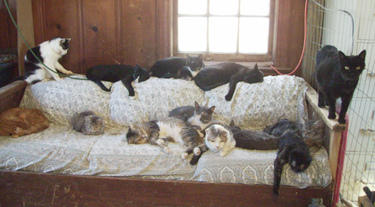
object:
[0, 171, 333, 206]
panel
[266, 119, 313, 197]
cat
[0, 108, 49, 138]
brown cat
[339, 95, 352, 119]
arm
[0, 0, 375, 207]
wall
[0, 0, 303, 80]
wood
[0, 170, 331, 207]
wood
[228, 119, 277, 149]
cat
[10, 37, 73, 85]
cat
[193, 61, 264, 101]
cat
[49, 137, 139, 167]
material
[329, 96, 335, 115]
arm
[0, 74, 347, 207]
couch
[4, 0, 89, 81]
cord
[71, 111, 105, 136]
cat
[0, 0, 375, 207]
room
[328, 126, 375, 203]
cage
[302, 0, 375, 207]
fence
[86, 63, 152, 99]
cat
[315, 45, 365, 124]
cat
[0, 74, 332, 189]
mattress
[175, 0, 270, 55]
window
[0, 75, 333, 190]
cushion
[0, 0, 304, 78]
paneled wall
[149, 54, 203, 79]
cat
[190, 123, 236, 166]
cat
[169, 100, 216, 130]
cat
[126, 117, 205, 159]
cat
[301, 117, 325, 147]
cats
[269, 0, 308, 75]
cord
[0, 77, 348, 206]
bed